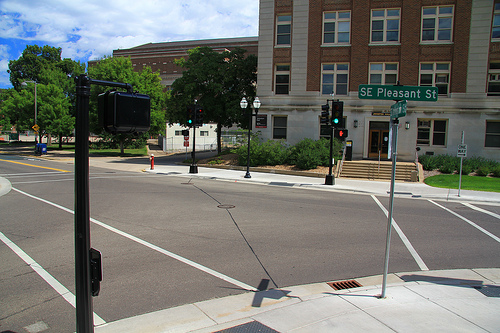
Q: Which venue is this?
A: This is a road.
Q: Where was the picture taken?
A: It was taken at the road.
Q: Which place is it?
A: It is a road.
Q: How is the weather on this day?
A: It is cloudy.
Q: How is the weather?
A: It is cloudy.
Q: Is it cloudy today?
A: Yes, it is cloudy.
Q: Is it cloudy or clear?
A: It is cloudy.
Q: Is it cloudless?
A: No, it is cloudy.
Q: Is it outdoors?
A: Yes, it is outdoors.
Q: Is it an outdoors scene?
A: Yes, it is outdoors.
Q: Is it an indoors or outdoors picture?
A: It is outdoors.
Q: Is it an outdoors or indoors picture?
A: It is outdoors.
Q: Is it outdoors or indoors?
A: It is outdoors.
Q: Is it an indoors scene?
A: No, it is outdoors.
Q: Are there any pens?
A: No, there are no pens.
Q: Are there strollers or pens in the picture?
A: No, there are no pens or strollers.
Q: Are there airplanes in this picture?
A: No, there are no airplanes.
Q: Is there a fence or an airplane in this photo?
A: No, there are no airplanes or fences.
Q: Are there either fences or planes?
A: No, there are no planes or fences.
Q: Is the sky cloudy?
A: Yes, the sky is cloudy.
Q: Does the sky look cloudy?
A: Yes, the sky is cloudy.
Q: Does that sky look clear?
A: No, the sky is cloudy.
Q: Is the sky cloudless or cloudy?
A: The sky is cloudy.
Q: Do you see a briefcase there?
A: No, there are no briefcases.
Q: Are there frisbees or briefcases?
A: No, there are no briefcases or frisbees.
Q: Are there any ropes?
A: No, there are no ropes.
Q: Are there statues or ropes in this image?
A: No, there are no ropes or statues.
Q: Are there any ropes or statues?
A: No, there are no ropes or statues.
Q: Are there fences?
A: No, there are no fences.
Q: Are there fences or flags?
A: No, there are no fences or flags.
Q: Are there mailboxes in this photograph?
A: No, there are no mailboxes.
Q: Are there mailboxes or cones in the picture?
A: No, there are no mailboxes or cones.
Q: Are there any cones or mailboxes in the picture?
A: No, there are no mailboxes or cones.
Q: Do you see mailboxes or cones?
A: No, there are no mailboxes or cones.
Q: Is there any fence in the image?
A: No, there are no fences.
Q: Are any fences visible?
A: No, there are no fences.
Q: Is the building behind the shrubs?
A: Yes, the building is behind the shrubs.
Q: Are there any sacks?
A: No, there are no sacks.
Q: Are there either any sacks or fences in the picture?
A: No, there are no sacks or fences.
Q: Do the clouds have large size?
A: Yes, the clouds are large.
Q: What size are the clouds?
A: The clouds are large.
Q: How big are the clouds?
A: The clouds are large.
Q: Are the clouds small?
A: No, the clouds are large.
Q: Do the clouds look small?
A: No, the clouds are large.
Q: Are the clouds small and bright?
A: No, the clouds are bright but large.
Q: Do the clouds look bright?
A: Yes, the clouds are bright.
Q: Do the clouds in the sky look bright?
A: Yes, the clouds are bright.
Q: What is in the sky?
A: The clouds are in the sky.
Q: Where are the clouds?
A: The clouds are in the sky.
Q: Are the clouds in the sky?
A: Yes, the clouds are in the sky.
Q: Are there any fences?
A: No, there are no fences.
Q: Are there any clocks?
A: No, there are no clocks.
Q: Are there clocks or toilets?
A: No, there are no clocks or toilets.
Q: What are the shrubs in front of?
A: The shrubs are in front of the building.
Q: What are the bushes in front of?
A: The shrubs are in front of the building.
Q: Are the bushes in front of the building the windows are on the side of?
A: Yes, the bushes are in front of the building.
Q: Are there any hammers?
A: No, there are no hammers.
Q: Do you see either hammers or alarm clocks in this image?
A: No, there are no hammers or alarm clocks.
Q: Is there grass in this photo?
A: Yes, there is grass.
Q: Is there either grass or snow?
A: Yes, there is grass.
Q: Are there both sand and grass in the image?
A: No, there is grass but no sand.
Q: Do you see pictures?
A: No, there are no pictures.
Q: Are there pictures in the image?
A: No, there are no pictures.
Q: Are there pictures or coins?
A: No, there are no pictures or coins.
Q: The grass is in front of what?
A: The grass is in front of the building.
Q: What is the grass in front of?
A: The grass is in front of the building.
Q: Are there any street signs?
A: Yes, there is a street sign.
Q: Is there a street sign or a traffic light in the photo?
A: Yes, there is a street sign.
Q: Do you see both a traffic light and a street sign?
A: Yes, there are both a street sign and a traffic light.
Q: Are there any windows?
A: Yes, there are windows.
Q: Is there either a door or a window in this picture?
A: Yes, there are windows.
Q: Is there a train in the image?
A: No, there are no trains.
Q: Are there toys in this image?
A: No, there are no toys.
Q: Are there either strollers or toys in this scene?
A: No, there are no toys or strollers.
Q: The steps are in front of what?
A: The steps are in front of the building.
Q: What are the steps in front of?
A: The steps are in front of the building.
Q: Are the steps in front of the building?
A: Yes, the steps are in front of the building.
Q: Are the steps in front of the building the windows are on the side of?
A: Yes, the steps are in front of the building.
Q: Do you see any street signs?
A: Yes, there is a street sign.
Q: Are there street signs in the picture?
A: Yes, there is a street sign.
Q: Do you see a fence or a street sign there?
A: Yes, there is a street sign.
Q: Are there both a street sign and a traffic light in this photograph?
A: Yes, there are both a street sign and a traffic light.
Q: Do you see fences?
A: No, there are no fences.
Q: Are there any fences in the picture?
A: No, there are no fences.